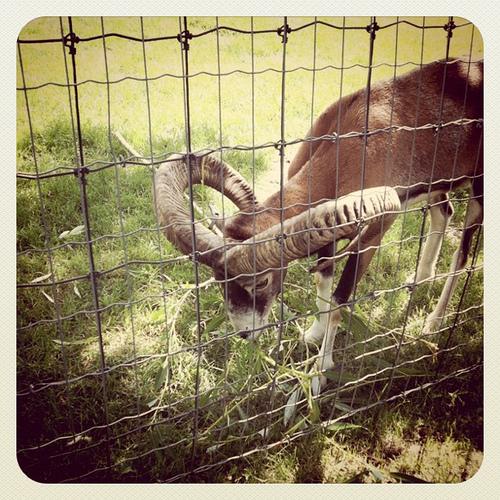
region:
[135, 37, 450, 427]
ram standing on the grass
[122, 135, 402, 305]
horns on top of the head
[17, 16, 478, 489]
green grass on the ground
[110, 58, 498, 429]
ram behind a fence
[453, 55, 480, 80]
light shining on the back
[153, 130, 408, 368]
head is bent down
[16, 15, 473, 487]
black wires on the fence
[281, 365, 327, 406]
grass poking through the fence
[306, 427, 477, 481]
light shining on the ground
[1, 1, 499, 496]
thick gray border around the scene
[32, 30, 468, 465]
straight and wavy lines of wire fencing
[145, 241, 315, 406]
goat eating plant by fence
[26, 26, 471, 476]
light green grass covering ground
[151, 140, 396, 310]
long curved horns over head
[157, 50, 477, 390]
tan fur over four-legged animal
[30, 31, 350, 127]
sun shining on grass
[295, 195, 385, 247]
dark oval ridges along outer horn edge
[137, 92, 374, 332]
neck bent down on animal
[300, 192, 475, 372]
white and dark brown legs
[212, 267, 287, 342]
dark open eye on narrowing head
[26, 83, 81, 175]
square of metal fence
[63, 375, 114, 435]
square of metal fence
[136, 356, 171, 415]
square of metal fence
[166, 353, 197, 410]
square of metal fence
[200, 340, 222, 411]
square of metal fence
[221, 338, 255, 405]
square of metal fence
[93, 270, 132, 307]
square of metal fence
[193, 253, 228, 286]
square of metal fence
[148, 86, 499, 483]
a goat behind a fence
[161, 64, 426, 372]
a metal fence in front of a goat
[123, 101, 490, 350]
a goat with long horns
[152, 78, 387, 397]
long horned goat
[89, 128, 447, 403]
a goat in a field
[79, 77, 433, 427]
a goat in a fenced in area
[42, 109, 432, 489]
a field of grass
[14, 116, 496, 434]
a field of green grass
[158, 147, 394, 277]
large horns on head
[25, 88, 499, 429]
wire fence to keep animal in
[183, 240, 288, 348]
animal eating the grass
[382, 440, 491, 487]
patches of light greens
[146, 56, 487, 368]
animal is large and long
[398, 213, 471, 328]
bottom part of legs are white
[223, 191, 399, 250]
horn on head is light brown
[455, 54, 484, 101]
patch of white on back